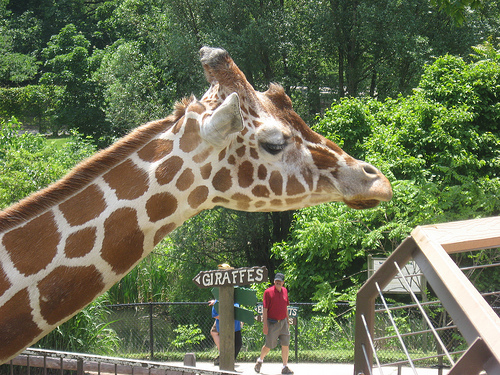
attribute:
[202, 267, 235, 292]
letter — white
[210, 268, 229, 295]
letter — white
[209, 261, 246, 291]
letter — white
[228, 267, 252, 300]
letter — white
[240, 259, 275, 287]
letter — white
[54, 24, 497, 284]
leaves — green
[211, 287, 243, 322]
shirt — blue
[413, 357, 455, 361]
tusk — blocked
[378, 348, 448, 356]
tusk — blocked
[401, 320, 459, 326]
tusk — blocked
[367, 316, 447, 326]
tusk — blocked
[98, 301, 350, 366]
fence — black chain link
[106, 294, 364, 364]
rail —  metal guard 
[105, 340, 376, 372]
path — cement 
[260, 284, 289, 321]
shirt — red